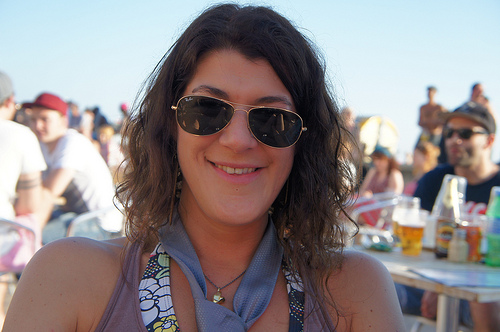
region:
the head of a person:
[23, 84, 71, 147]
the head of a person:
[433, 97, 495, 174]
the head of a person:
[418, 83, 440, 108]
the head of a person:
[470, 78, 487, 100]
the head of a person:
[363, 137, 400, 182]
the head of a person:
[336, 102, 358, 129]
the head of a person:
[0, 80, 21, 117]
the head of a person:
[112, 98, 129, 115]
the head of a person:
[90, 113, 113, 140]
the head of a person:
[98, 2, 353, 260]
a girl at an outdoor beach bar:
[31, 13, 433, 328]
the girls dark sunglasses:
[155, 83, 327, 178]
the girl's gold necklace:
[195, 255, 250, 312]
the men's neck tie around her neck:
[156, 213, 291, 329]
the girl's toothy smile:
[200, 154, 275, 186]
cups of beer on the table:
[380, 165, 438, 273]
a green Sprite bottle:
[482, 182, 498, 282]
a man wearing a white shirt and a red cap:
[19, 86, 116, 232]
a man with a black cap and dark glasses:
[415, 93, 493, 221]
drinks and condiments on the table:
[365, 173, 498, 272]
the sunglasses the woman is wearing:
[166, 86, 314, 157]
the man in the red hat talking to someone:
[1, 67, 112, 244]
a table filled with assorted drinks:
[394, 167, 499, 269]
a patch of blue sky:
[5, 1, 166, 105]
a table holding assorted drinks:
[375, 223, 498, 313]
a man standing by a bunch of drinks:
[406, 100, 499, 208]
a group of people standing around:
[343, 80, 497, 196]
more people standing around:
[0, 78, 122, 231]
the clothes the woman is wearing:
[116, 222, 315, 330]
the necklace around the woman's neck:
[207, 280, 235, 308]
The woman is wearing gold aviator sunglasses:
[82, 8, 419, 316]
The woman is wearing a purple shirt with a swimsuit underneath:
[92, 9, 359, 327]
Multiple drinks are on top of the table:
[379, 117, 491, 284]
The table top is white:
[363, 166, 493, 320]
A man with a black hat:
[403, 99, 489, 195]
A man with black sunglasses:
[401, 89, 497, 226]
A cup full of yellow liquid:
[378, 200, 433, 266]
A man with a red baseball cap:
[21, 76, 128, 246]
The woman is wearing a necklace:
[83, 15, 360, 326]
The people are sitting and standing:
[364, 67, 489, 254]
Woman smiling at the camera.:
[109, 0, 371, 267]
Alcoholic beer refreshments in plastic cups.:
[378, 185, 440, 262]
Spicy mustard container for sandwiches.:
[442, 222, 483, 270]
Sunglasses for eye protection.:
[154, 74, 321, 161]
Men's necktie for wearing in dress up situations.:
[136, 180, 316, 330]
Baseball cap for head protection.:
[19, 84, 77, 123]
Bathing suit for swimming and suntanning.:
[126, 224, 338, 329]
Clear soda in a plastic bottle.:
[479, 180, 498, 272]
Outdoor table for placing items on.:
[349, 235, 499, 329]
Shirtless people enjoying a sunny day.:
[409, 72, 498, 180]